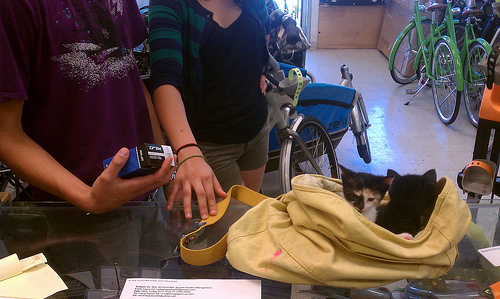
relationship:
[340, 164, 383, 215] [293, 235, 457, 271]
kitten in backpack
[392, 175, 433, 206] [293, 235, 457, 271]
kitten in backpack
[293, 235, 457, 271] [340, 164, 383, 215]
backpack has kitten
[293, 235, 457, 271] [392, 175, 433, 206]
backpack has kitten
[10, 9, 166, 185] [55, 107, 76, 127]
person wearing shirt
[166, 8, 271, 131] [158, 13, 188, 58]
person wearing sweater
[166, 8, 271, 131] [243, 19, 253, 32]
person wearing shirt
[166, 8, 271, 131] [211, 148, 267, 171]
person wearing shorts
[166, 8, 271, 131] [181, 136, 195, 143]
person has wrist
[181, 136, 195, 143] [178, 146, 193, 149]
wrist has elastic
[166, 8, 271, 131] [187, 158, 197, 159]
person wearing bracelet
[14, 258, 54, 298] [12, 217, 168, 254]
paper on counter top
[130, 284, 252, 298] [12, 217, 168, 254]
paper on counter top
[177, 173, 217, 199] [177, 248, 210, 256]
hand reaching for handle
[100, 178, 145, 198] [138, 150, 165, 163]
hand holding box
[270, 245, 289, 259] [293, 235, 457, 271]
smudge on backpack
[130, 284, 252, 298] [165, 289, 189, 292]
paper has writing